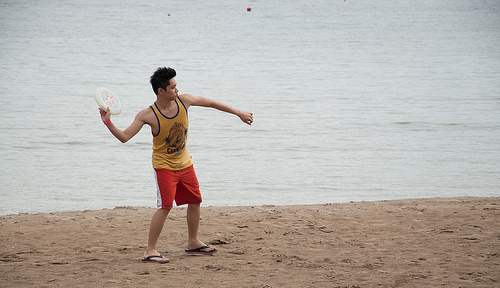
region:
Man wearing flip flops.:
[133, 240, 222, 265]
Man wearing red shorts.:
[144, 151, 205, 212]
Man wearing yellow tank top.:
[145, 96, 193, 181]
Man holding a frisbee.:
[95, 68, 199, 140]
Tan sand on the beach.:
[283, 210, 464, 265]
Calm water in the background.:
[292, 46, 429, 147]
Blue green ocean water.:
[263, 46, 408, 103]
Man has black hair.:
[147, 66, 177, 109]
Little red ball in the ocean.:
[225, 3, 267, 21]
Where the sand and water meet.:
[305, 176, 455, 223]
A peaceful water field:
[1, 4, 496, 214]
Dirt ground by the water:
[1, 197, 499, 285]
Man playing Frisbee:
[97, 66, 254, 263]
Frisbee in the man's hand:
[93, 88, 123, 115]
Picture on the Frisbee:
[101, 89, 119, 109]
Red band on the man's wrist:
[102, 120, 112, 126]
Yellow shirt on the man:
[150, 99, 195, 171]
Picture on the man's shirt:
[162, 122, 189, 155]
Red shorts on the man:
[152, 166, 202, 211]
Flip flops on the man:
[140, 240, 219, 264]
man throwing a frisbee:
[88, 57, 263, 264]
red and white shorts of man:
[152, 169, 199, 208]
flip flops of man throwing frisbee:
[137, 242, 216, 266]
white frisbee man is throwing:
[93, 86, 118, 114]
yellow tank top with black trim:
[148, 105, 195, 170]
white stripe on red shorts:
[152, 169, 164, 209]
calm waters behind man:
[5, 7, 497, 194]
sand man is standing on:
[18, 209, 495, 286]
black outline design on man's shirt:
[161, 121, 187, 152]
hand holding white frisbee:
[91, 102, 110, 125]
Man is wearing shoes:
[135, 241, 222, 265]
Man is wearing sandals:
[137, 240, 219, 265]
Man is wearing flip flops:
[135, 240, 219, 266]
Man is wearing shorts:
[147, 160, 207, 210]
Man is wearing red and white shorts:
[148, 160, 205, 211]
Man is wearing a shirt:
[146, 95, 196, 175]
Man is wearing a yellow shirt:
[141, 90, 196, 175]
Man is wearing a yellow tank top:
[145, 91, 195, 171]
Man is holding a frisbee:
[94, 82, 124, 117]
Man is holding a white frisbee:
[90, 85, 125, 115]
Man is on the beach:
[94, 54, 256, 256]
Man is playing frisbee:
[92, 67, 257, 258]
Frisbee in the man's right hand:
[76, 71, 126, 127]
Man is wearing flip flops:
[127, 222, 240, 267]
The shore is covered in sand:
[237, 207, 499, 285]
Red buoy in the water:
[234, 5, 263, 15]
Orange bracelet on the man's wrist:
[94, 112, 135, 131]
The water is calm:
[289, 45, 490, 177]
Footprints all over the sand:
[251, 199, 455, 280]